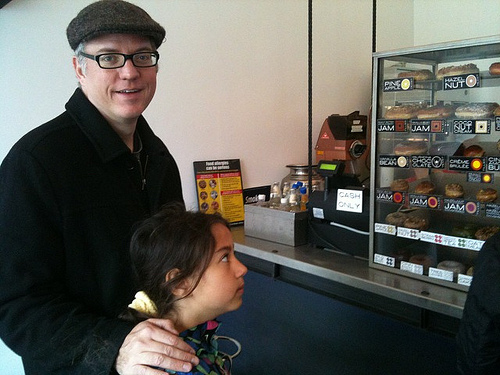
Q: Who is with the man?
A: A girl.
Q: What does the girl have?
A: Hair.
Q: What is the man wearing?
A: Jacket.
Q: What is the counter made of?
A: Metal.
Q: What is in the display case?
A: Pastries.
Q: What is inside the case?
A: Pastries.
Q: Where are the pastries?
A: Case.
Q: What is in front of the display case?
A: Shelf.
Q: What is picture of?
A: Father and daughter at store.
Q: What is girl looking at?
A: Yummy food.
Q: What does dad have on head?
A: Cap.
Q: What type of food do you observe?
A: Yummy desserts.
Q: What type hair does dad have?
A: Gray and short.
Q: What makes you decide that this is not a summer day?
A: Dad long sleeve and cap.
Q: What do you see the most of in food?
A: Donuts.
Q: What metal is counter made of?
A: Stainless steel.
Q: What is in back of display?
A: White wall.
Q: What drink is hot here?
A: Coffee.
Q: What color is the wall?
A: White.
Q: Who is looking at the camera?
A: The man.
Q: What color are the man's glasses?
A: Black.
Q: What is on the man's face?
A: Glasses.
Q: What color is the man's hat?
A: Gray.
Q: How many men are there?
A: One.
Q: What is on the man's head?
A: A hat.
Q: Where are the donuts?
A: On the counter.